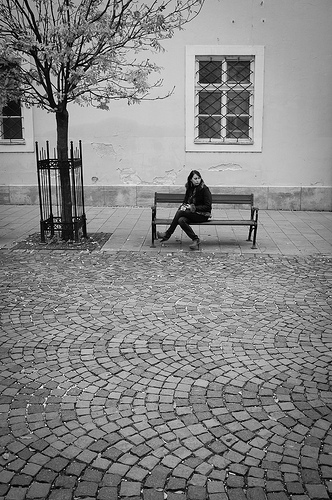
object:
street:
[0, 250, 331, 497]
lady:
[157, 169, 213, 251]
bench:
[149, 190, 259, 248]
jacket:
[182, 184, 212, 216]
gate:
[34, 139, 90, 239]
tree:
[0, 1, 210, 242]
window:
[191, 46, 261, 154]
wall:
[0, 1, 331, 212]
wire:
[196, 52, 253, 143]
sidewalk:
[0, 203, 331, 257]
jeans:
[167, 203, 211, 239]